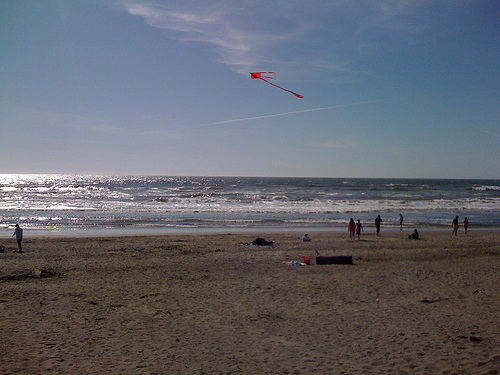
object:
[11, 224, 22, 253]
person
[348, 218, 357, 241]
person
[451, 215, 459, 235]
person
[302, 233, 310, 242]
someone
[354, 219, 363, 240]
person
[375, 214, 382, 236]
person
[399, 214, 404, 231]
person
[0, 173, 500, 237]
ocean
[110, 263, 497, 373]
sand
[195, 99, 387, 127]
trail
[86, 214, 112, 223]
ripple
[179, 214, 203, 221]
ripple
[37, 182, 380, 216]
ripple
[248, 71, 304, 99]
kite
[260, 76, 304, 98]
tail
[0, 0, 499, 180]
sky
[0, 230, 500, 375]
beach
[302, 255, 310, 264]
bucket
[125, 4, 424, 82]
cloud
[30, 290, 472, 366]
foot prints